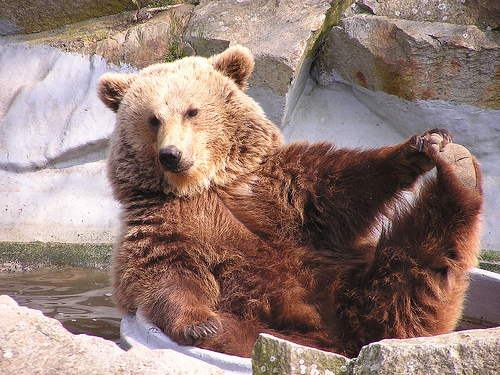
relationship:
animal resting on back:
[95, 43, 484, 359] [105, 220, 263, 365]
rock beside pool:
[250, 330, 357, 373] [1, 226, 493, 374]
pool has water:
[1, 226, 493, 374] [0, 254, 167, 344]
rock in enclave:
[307, 0, 500, 155] [3, 5, 491, 363]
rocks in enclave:
[197, 9, 344, 114] [3, 5, 491, 363]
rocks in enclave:
[0, 0, 333, 88] [3, 5, 491, 363]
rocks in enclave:
[10, 102, 110, 234] [3, 5, 491, 363]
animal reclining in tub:
[95, 43, 484, 359] [110, 238, 476, 372]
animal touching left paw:
[95, 43, 484, 359] [327, 145, 454, 196]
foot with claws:
[426, 127, 491, 208] [417, 125, 483, 204]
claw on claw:
[195, 325, 207, 336] [195, 325, 207, 336]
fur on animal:
[148, 221, 257, 296] [95, 43, 484, 359]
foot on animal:
[426, 132, 483, 207] [95, 43, 484, 359]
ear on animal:
[90, 70, 135, 111] [95, 43, 484, 359]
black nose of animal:
[159, 145, 183, 168] [95, 43, 484, 359]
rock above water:
[307, 1, 498, 155] [0, 263, 500, 373]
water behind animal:
[2, 263, 124, 338] [95, 43, 484, 359]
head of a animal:
[95, 44, 274, 197] [95, 43, 484, 359]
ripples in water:
[60, 312, 120, 328] [4, 248, 102, 291]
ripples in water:
[60, 312, 120, 328] [6, 270, 117, 328]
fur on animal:
[148, 221, 257, 296] [95, 37, 482, 373]